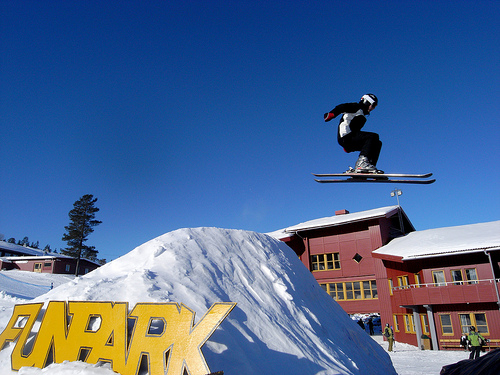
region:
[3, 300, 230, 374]
The word funpark.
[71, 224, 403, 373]
Huge pile of snow.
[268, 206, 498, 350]
Red building with lots of windows.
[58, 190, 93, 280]
Tall evergreen tree in front of a building.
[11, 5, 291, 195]
clear blue sky with no clouds.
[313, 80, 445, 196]
A skier with his arms behind him.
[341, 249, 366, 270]
A diamond shaped window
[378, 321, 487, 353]
People standing beside the building.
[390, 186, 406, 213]
Spotlight on top of the building.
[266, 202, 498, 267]
Snow covered roof tops.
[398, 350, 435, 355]
white snow on the ground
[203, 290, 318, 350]
shadow cast on the mound of snow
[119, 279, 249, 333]
black edge of yellow sign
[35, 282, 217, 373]
yellow words in front of the snow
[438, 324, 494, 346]
skier wearing green jacket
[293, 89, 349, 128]
black and red gloves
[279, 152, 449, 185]
blue and red skis on skier's foot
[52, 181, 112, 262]
large green tree in the background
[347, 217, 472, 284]
snow on the roof top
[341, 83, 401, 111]
black and white helmet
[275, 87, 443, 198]
the man is in the air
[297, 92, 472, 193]
the man is on skis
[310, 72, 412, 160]
the man's clothes are black and white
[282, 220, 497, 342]
the building is red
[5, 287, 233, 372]
the letters are yellow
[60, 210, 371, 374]
the snow has formed a hill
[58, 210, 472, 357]
the snow is white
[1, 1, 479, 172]
the sky is blue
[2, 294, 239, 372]
the letters are against the snow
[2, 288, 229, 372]
the letters spell anpark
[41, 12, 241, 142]
The sky is blue.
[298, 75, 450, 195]
The person on skis is jumping through the air.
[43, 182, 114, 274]
A green pine tree.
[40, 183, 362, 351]
A small mound of snow.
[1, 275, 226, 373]
The yellow letters say Funpark.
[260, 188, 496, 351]
The building is red.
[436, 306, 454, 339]
A window on the building.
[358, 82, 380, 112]
The skier is wearing a helmet.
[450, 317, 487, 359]
A person is standing in the distance.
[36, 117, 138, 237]
The sky above the pine tree is blue.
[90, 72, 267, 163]
the sky is blue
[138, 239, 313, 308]
the snow is white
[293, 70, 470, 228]
the person is skiing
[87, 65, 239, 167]
the sky is clear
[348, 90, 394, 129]
person is wearing helmet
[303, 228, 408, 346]
the building is red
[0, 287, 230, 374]
the text is yellow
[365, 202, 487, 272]
the roof is white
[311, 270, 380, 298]
the window pane is yellow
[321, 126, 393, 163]
the pants are black